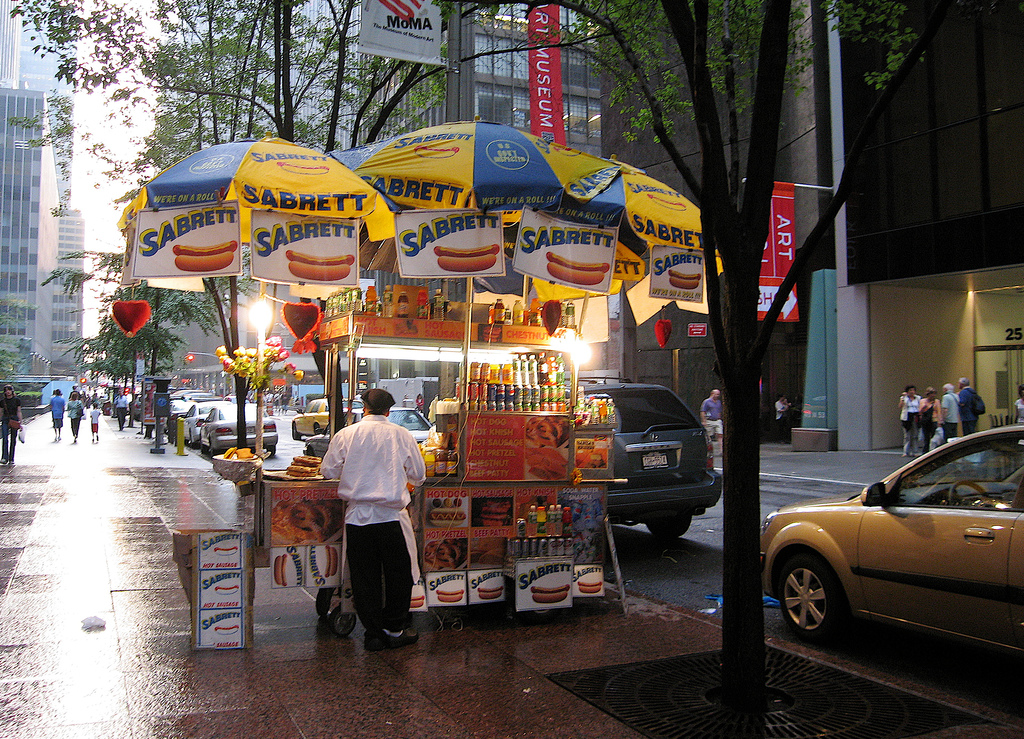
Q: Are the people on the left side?
A: Yes, the people are on the left of the image.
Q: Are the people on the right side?
A: No, the people are on the left of the image.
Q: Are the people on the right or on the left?
A: The people are on the left of the image.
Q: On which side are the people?
A: The people are on the left of the image.